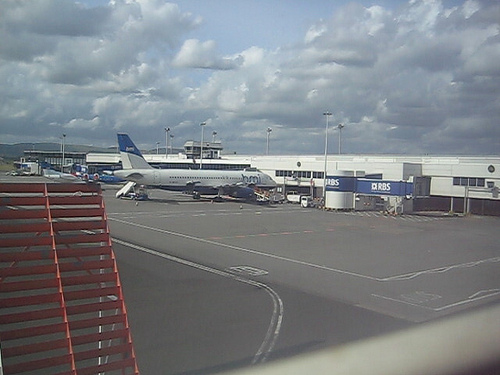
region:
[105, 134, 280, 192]
blue and white plane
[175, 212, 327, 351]
white lines on tarmac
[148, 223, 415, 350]
tarmac is dark grey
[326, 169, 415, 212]
blue and white logo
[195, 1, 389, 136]
blue and white sky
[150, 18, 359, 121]
heavy white clouds in sky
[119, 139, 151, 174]
blue and white tail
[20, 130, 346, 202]
tall light posts around building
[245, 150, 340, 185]
black windows on building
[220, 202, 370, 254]
red lines on tarmac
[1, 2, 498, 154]
these are dark clouds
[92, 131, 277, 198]
this is a airplane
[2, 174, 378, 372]
this is the runway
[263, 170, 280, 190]
thats the nose of the plane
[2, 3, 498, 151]
thats the clouds in the sky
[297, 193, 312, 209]
thats a garbage can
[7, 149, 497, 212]
these are the buildings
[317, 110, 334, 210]
thats a pole light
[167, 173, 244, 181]
these are windows on plane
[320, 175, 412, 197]
these are blue letters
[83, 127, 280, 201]
An airplane on the terminal.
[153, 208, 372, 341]
White lines on the pavement.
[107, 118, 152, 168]
The tail of the plane is blue and white.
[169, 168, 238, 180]
Windows on the plane.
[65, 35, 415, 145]
Dark clouds in the sky.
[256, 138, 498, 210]
The terminal of the airport.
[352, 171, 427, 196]
A blue terminal walkway.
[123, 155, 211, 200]
The plane is white.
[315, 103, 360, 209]
Lights by the building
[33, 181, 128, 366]
A red object on the runway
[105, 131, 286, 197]
large airplane parked at airport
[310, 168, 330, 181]
window on the large white building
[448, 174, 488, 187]
window on the large white building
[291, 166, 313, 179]
window on the large white building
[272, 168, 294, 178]
window on the large white building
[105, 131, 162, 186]
tail section of the large airplane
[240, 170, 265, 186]
blue logo on the white airplane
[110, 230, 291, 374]
white line painted on the tarmac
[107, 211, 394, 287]
white line painted on the tarmac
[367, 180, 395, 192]
white logo painted on the building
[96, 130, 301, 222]
airplane parked in an airport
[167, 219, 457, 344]
white lines on the cement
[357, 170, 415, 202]
blue and white sign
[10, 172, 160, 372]
red steel tall structure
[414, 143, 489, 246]
white exterior building of an airport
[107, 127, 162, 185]
blue and white tail of an airplane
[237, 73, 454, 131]
cloudy gray and white sky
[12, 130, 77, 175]
large mountains in the distance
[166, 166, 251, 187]
lots of dark windows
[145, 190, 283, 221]
airplane shadow on the grown